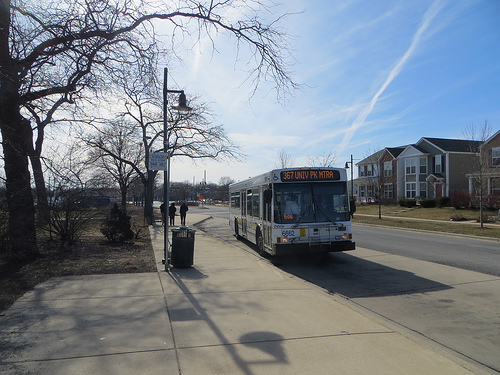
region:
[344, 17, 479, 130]
this is the sky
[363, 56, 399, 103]
the sky is blue in color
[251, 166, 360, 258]
this is a bus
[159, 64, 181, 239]
this is a pole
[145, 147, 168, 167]
this is a signpost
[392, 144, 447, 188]
this is a building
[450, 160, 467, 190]
this is the wall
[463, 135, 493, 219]
this is a tree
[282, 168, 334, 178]
the text is yellow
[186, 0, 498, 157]
whispy clouds in sky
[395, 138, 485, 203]
the house is big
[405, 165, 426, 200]
windows on front of house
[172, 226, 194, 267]
trash can on side walk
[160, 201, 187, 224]
people are walking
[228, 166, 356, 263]
the bus is driving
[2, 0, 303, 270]
trees have no leaves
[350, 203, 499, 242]
some strips of grass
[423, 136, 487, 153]
the roof is dark brown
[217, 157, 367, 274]
bus on the road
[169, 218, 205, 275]
trash can on the sidewalk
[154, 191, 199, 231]
people walking down the sidewalk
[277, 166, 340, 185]
digital writing on the top of the bus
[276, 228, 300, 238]
numbers on the bus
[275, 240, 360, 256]
black bumper on the front of the bus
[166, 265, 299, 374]
shadow on the sidewalk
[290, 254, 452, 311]
shadow from the bus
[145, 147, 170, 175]
sign on the pole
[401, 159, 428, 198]
windows on the building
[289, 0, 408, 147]
a few thin clouds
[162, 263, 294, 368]
a shadow on the sidewalk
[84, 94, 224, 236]
a few trees bare of leaves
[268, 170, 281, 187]
a blue handicap sign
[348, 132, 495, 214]
a few two story houses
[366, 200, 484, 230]
a sidewalk between lawns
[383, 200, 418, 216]
a few large steps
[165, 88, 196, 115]
a metal street lamp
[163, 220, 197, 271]
a metal trash can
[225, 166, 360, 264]
a white city bus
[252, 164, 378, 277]
bus is on the highway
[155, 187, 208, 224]
pople walking next to the buss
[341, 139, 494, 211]
building are adjacent to the road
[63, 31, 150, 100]
trees are dried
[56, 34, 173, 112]
trees are brown in color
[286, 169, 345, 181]
the words are written in yellow color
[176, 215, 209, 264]
the dust bin next to the street light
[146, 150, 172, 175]
poster is white in color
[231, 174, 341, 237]
bus is white in color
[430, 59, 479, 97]
the sky is clear light blue in color